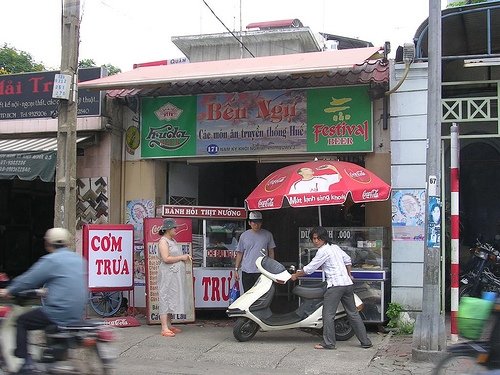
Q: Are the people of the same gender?
A: No, they are both male and female.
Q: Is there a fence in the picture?
A: No, there are no fences.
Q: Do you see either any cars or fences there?
A: No, there are no fences or cars.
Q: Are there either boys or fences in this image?
A: No, there are no boys or fences.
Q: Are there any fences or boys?
A: No, there are no boys or fences.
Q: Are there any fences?
A: No, there are no fences.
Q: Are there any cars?
A: No, there are no cars.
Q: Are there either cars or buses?
A: No, there are no cars or buses.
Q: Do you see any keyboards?
A: Yes, there is a keyboard.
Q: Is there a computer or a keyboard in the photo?
A: Yes, there is a keyboard.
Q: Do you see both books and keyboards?
A: No, there is a keyboard but no books.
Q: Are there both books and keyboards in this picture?
A: No, there is a keyboard but no books.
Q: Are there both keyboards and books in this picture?
A: No, there is a keyboard but no books.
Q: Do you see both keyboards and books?
A: No, there is a keyboard but no books.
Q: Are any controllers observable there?
A: No, there are no controllers.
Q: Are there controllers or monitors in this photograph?
A: No, there are no controllers or monitors.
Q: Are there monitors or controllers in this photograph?
A: No, there are no controllers or monitors.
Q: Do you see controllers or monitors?
A: No, there are no controllers or monitors.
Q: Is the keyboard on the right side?
A: Yes, the keyboard is on the right of the image.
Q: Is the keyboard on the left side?
A: No, the keyboard is on the right of the image.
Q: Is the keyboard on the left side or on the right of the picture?
A: The keyboard is on the right of the image.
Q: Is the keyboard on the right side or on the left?
A: The keyboard is on the right of the image.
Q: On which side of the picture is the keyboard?
A: The keyboard is on the right of the image.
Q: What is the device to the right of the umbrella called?
A: The device is a keyboard.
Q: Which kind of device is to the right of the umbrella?
A: The device is a keyboard.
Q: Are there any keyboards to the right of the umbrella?
A: Yes, there is a keyboard to the right of the umbrella.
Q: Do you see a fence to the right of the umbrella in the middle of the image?
A: No, there is a keyboard to the right of the umbrella.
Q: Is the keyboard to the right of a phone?
A: No, the keyboard is to the right of the umbrella.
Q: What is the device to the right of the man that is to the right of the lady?
A: The device is a keyboard.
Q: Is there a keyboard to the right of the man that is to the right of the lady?
A: Yes, there is a keyboard to the right of the man.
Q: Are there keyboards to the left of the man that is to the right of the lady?
A: No, the keyboard is to the right of the man.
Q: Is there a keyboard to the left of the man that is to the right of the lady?
A: No, the keyboard is to the right of the man.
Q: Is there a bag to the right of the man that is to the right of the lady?
A: No, there is a keyboard to the right of the man.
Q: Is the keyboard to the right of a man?
A: Yes, the keyboard is to the right of a man.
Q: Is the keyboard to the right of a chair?
A: No, the keyboard is to the right of a man.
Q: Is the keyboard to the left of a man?
A: No, the keyboard is to the right of a man.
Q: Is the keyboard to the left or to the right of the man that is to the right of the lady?
A: The keyboard is to the right of the man.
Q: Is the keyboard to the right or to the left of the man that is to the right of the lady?
A: The keyboard is to the right of the man.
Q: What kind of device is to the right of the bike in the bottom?
A: The device is a keyboard.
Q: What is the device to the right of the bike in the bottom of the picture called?
A: The device is a keyboard.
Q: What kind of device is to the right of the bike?
A: The device is a keyboard.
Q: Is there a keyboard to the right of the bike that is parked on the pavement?
A: Yes, there is a keyboard to the right of the bike.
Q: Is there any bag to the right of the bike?
A: No, there is a keyboard to the right of the bike.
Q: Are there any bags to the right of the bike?
A: No, there is a keyboard to the right of the bike.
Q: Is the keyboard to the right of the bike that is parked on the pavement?
A: Yes, the keyboard is to the right of the bike.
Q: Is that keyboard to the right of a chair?
A: No, the keyboard is to the right of the bike.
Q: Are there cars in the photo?
A: No, there are no cars.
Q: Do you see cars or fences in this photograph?
A: No, there are no cars or fences.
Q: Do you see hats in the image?
A: Yes, there is a hat.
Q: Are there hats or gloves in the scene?
A: Yes, there is a hat.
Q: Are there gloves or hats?
A: Yes, there is a hat.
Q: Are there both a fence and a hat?
A: No, there is a hat but no fences.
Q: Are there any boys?
A: No, there are no boys.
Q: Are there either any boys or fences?
A: No, there are no boys or fences.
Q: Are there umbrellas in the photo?
A: Yes, there is an umbrella.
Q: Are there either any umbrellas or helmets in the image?
A: Yes, there is an umbrella.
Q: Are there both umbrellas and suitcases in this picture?
A: No, there is an umbrella but no suitcases.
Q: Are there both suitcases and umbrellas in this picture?
A: No, there is an umbrella but no suitcases.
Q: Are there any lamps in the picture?
A: No, there are no lamps.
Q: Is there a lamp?
A: No, there are no lamps.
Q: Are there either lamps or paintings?
A: No, there are no lamps or paintings.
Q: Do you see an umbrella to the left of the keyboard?
A: Yes, there is an umbrella to the left of the keyboard.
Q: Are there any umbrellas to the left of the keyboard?
A: Yes, there is an umbrella to the left of the keyboard.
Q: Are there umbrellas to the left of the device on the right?
A: Yes, there is an umbrella to the left of the keyboard.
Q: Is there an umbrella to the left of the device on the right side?
A: Yes, there is an umbrella to the left of the keyboard.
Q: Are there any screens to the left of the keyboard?
A: No, there is an umbrella to the left of the keyboard.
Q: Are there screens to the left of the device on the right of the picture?
A: No, there is an umbrella to the left of the keyboard.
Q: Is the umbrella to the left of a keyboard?
A: Yes, the umbrella is to the left of a keyboard.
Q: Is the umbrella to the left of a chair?
A: No, the umbrella is to the left of a keyboard.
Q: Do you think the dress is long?
A: Yes, the dress is long.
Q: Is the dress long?
A: Yes, the dress is long.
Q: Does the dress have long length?
A: Yes, the dress is long.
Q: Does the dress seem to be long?
A: Yes, the dress is long.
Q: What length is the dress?
A: The dress is long.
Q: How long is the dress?
A: The dress is long.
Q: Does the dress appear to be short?
A: No, the dress is long.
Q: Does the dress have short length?
A: No, the dress is long.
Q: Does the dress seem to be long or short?
A: The dress is long.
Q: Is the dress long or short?
A: The dress is long.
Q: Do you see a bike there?
A: Yes, there is a bike.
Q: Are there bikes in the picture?
A: Yes, there is a bike.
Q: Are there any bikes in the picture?
A: Yes, there is a bike.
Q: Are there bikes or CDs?
A: Yes, there is a bike.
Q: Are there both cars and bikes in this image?
A: No, there is a bike but no cars.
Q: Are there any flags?
A: No, there are no flags.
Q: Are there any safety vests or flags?
A: No, there are no flags or safety vests.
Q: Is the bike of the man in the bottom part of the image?
A: Yes, the bike is in the bottom of the image.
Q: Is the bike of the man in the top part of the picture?
A: No, the bike is in the bottom of the image.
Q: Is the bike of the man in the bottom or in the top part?
A: The bike is in the bottom of the image.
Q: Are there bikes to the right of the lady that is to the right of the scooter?
A: Yes, there is a bike to the right of the lady.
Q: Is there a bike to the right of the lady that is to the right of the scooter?
A: Yes, there is a bike to the right of the lady.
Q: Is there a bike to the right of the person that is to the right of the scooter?
A: Yes, there is a bike to the right of the lady.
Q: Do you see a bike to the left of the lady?
A: No, the bike is to the right of the lady.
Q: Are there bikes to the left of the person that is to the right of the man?
A: No, the bike is to the right of the lady.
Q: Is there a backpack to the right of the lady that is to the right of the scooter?
A: No, there is a bike to the right of the lady.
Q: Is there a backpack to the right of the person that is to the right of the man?
A: No, there is a bike to the right of the lady.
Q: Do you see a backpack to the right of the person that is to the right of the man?
A: No, there is a bike to the right of the lady.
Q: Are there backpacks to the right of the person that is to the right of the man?
A: No, there is a bike to the right of the lady.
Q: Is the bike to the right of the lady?
A: Yes, the bike is to the right of the lady.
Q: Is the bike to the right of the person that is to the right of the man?
A: Yes, the bike is to the right of the lady.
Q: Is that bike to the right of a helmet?
A: No, the bike is to the right of the lady.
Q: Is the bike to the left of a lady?
A: No, the bike is to the right of a lady.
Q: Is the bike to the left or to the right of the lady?
A: The bike is to the right of the lady.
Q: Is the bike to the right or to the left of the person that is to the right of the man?
A: The bike is to the right of the lady.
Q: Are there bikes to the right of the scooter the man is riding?
A: Yes, there is a bike to the right of the scooter.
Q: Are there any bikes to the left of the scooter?
A: No, the bike is to the right of the scooter.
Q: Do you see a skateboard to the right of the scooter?
A: No, there is a bike to the right of the scooter.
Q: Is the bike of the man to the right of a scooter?
A: Yes, the bike is to the right of a scooter.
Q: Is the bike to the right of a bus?
A: No, the bike is to the right of a scooter.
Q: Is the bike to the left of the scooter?
A: No, the bike is to the right of the scooter.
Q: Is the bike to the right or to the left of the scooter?
A: The bike is to the right of the scooter.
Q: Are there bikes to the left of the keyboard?
A: Yes, there is a bike to the left of the keyboard.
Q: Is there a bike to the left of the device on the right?
A: Yes, there is a bike to the left of the keyboard.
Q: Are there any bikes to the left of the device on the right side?
A: Yes, there is a bike to the left of the keyboard.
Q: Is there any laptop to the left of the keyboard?
A: No, there is a bike to the left of the keyboard.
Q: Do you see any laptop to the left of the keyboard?
A: No, there is a bike to the left of the keyboard.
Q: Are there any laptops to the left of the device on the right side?
A: No, there is a bike to the left of the keyboard.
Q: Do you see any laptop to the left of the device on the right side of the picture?
A: No, there is a bike to the left of the keyboard.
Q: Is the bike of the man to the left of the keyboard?
A: Yes, the bike is to the left of the keyboard.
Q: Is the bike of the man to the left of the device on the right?
A: Yes, the bike is to the left of the keyboard.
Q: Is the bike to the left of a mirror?
A: No, the bike is to the left of the keyboard.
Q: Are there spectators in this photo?
A: No, there are no spectators.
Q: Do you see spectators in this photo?
A: No, there are no spectators.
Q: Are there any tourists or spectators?
A: No, there are no spectators or tourists.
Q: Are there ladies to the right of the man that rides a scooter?
A: Yes, there is a lady to the right of the man.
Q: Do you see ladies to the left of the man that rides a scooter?
A: No, the lady is to the right of the man.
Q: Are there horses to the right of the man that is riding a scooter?
A: No, there is a lady to the right of the man.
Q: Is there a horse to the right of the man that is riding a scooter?
A: No, there is a lady to the right of the man.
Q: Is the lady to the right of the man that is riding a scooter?
A: Yes, the lady is to the right of the man.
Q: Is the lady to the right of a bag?
A: No, the lady is to the right of the man.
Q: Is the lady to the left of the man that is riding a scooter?
A: No, the lady is to the right of the man.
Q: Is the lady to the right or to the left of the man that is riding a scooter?
A: The lady is to the right of the man.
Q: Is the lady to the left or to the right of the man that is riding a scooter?
A: The lady is to the right of the man.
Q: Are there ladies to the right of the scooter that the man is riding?
A: Yes, there is a lady to the right of the scooter.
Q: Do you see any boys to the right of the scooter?
A: No, there is a lady to the right of the scooter.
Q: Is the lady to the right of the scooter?
A: Yes, the lady is to the right of the scooter.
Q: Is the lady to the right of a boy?
A: No, the lady is to the right of the scooter.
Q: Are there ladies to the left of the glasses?
A: Yes, there is a lady to the left of the glasses.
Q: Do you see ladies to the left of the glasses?
A: Yes, there is a lady to the left of the glasses.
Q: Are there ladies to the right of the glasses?
A: No, the lady is to the left of the glasses.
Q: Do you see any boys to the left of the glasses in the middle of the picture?
A: No, there is a lady to the left of the glasses.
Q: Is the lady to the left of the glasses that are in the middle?
A: Yes, the lady is to the left of the glasses.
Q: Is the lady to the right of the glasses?
A: No, the lady is to the left of the glasses.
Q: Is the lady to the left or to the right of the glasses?
A: The lady is to the left of the glasses.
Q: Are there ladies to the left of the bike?
A: Yes, there is a lady to the left of the bike.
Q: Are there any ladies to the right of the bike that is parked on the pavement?
A: No, the lady is to the left of the bike.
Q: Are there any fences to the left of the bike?
A: No, there is a lady to the left of the bike.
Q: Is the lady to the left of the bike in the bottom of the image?
A: Yes, the lady is to the left of the bike.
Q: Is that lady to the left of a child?
A: No, the lady is to the left of the bike.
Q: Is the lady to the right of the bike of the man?
A: No, the lady is to the left of the bike.